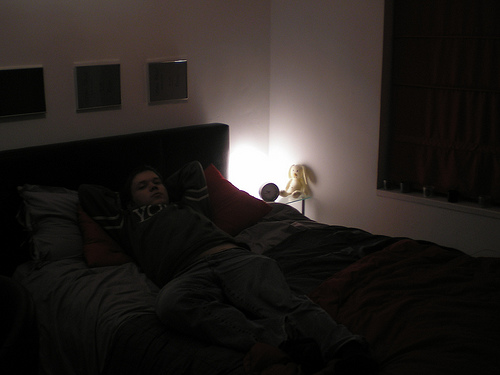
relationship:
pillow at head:
[22, 181, 96, 268] [24, 142, 255, 232]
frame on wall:
[149, 64, 184, 95] [254, 43, 344, 170]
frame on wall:
[65, 55, 130, 113] [254, 43, 344, 170]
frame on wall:
[3, 82, 44, 118] [254, 43, 344, 170]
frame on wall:
[75, 60, 123, 109] [4, 7, 262, 190]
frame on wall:
[153, 59, 190, 102] [4, 7, 262, 190]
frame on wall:
[0, 65, 44, 115] [4, 7, 262, 190]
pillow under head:
[184, 160, 267, 229] [124, 168, 171, 205]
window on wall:
[393, 0, 497, 203] [272, 0, 384, 224]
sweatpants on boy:
[161, 237, 364, 362] [77, 160, 384, 373]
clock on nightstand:
[255, 179, 279, 200] [239, 175, 310, 220]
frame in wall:
[75, 60, 123, 109] [258, 22, 375, 156]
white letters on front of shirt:
[131, 200, 181, 225] [101, 177, 252, 292]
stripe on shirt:
[183, 194, 220, 202] [114, 199, 244, 271]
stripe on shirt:
[184, 179, 211, 193] [114, 199, 244, 271]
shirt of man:
[114, 199, 244, 271] [65, 163, 254, 277]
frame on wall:
[0, 65, 44, 115] [0, 3, 277, 208]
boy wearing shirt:
[77, 160, 384, 373] [74, 160, 258, 287]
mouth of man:
[149, 189, 166, 200] [69, 153, 416, 373]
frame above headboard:
[153, 59, 190, 102] [0, 117, 230, 272]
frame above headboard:
[75, 60, 123, 109] [0, 117, 230, 272]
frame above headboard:
[0, 65, 44, 115] [0, 117, 230, 272]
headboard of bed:
[0, 117, 230, 272] [9, 119, 498, 372]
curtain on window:
[380, 3, 498, 197] [377, 6, 497, 212]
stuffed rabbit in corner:
[275, 162, 312, 199] [225, 0, 306, 200]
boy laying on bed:
[99, 141, 206, 256] [27, 164, 375, 322]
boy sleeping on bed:
[77, 160, 384, 373] [9, 119, 498, 372]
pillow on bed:
[74, 160, 275, 269] [9, 119, 498, 372]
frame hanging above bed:
[153, 59, 190, 102] [50, 110, 454, 361]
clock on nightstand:
[259, 183, 280, 204] [238, 178, 312, 216]